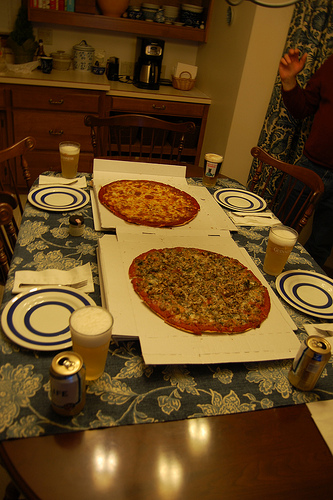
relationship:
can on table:
[49, 350, 87, 419] [3, 168, 332, 498]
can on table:
[44, 344, 88, 419] [3, 168, 332, 498]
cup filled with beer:
[263, 222, 301, 272] [47, 352, 88, 419]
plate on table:
[29, 184, 90, 210] [3, 168, 332, 498]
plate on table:
[214, 187, 267, 213] [3, 168, 332, 498]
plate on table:
[274, 269, 332, 319] [3, 168, 332, 498]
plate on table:
[0, 282, 99, 354] [3, 168, 332, 498]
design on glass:
[206, 165, 215, 183] [202, 152, 222, 185]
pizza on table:
[98, 179, 198, 228] [35, 172, 326, 498]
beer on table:
[63, 138, 244, 186] [35, 172, 326, 498]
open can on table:
[50, 350, 88, 418] [3, 168, 332, 498]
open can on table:
[286, 334, 330, 390] [3, 168, 332, 498]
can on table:
[49, 350, 87, 419] [0, 134, 332, 493]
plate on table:
[210, 181, 267, 217] [3, 168, 332, 498]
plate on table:
[0, 282, 99, 354] [3, 138, 332, 419]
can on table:
[49, 350, 87, 419] [30, 129, 322, 390]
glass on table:
[62, 302, 118, 381] [6, 177, 90, 306]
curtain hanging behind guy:
[270, 62, 303, 185] [265, 36, 331, 153]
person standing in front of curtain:
[274, 45, 331, 274] [243, 2, 330, 221]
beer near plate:
[258, 223, 301, 278] [271, 267, 332, 311]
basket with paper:
[171, 71, 193, 90] [174, 62, 197, 80]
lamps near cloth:
[82, 426, 214, 487] [133, 369, 210, 411]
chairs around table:
[4, 119, 330, 245] [3, 168, 332, 498]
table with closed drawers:
[3, 168, 332, 498] [16, 84, 102, 175]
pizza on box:
[98, 179, 198, 228] [89, 152, 239, 244]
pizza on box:
[129, 247, 271, 334] [104, 228, 293, 355]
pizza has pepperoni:
[98, 179, 198, 228] [133, 190, 141, 195]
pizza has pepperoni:
[98, 179, 198, 228] [145, 194, 154, 199]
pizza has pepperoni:
[98, 179, 198, 228] [134, 185, 143, 188]